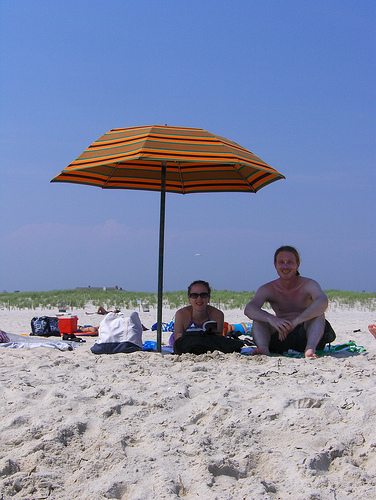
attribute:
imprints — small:
[98, 481, 135, 496]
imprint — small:
[206, 464, 240, 491]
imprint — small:
[307, 448, 346, 468]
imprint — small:
[285, 397, 323, 409]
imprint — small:
[59, 431, 80, 448]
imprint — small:
[106, 481, 129, 499]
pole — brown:
[156, 160, 167, 352]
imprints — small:
[62, 365, 207, 455]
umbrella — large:
[48, 124, 282, 192]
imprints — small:
[203, 458, 256, 491]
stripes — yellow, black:
[147, 133, 197, 141]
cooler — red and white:
[53, 306, 88, 333]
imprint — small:
[58, 420, 87, 448]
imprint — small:
[207, 459, 249, 478]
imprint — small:
[307, 445, 341, 473]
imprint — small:
[281, 397, 320, 406]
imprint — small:
[101, 396, 135, 422]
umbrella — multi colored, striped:
[50, 127, 286, 196]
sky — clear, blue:
[2, 3, 374, 125]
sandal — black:
[63, 333, 85, 342]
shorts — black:
[263, 313, 340, 355]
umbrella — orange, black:
[39, 112, 304, 226]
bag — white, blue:
[90, 311, 143, 352]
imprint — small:
[280, 393, 327, 412]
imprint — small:
[17, 378, 35, 389]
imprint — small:
[102, 476, 137, 498]